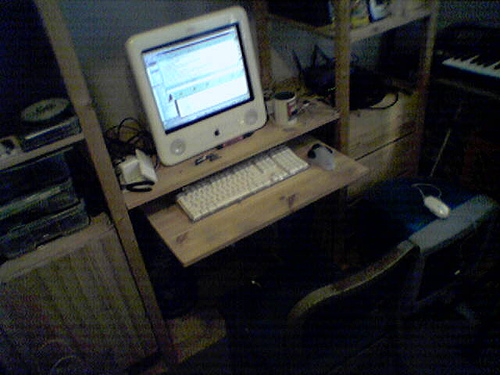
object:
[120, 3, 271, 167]
computer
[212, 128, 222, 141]
apple